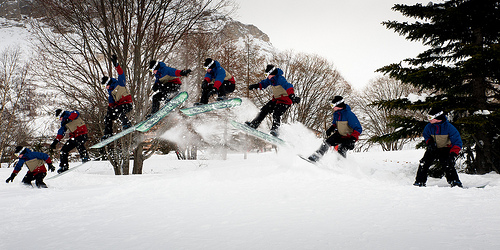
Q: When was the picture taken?
A: Daytime.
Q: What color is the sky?
A: White.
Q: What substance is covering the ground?
A: Snow.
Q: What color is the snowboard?
A: Green.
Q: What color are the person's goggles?
A: White.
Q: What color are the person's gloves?
A: Red.